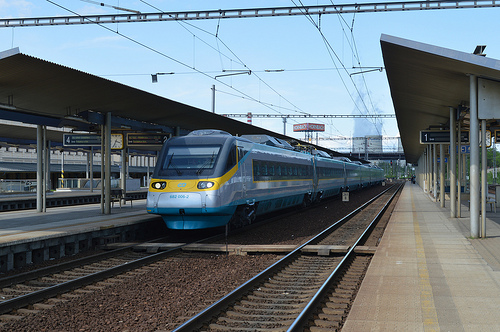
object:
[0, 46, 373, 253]
platform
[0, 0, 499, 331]
station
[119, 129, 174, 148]
sign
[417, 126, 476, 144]
sign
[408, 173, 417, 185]
people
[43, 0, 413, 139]
wires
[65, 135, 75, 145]
number 4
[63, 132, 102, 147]
sign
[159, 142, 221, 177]
window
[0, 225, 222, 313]
tracks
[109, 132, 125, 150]
clock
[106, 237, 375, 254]
track beam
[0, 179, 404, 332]
rocks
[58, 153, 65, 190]
pole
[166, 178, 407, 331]
rail road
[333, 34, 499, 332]
platform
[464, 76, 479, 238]
columns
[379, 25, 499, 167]
roof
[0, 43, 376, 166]
roof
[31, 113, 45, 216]
columns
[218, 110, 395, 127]
structure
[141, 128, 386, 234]
train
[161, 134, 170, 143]
number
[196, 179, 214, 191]
headlight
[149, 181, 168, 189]
headlight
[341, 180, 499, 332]
walkway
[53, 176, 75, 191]
stripes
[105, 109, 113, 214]
column